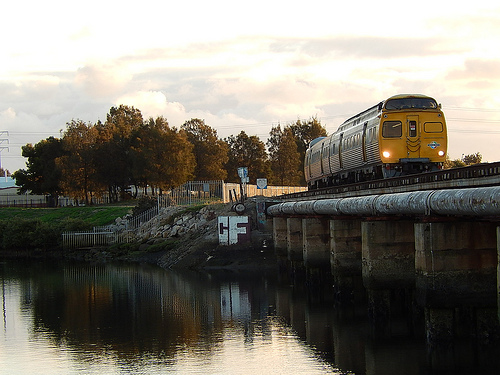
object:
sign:
[256, 178, 269, 190]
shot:
[0, 0, 499, 374]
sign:
[236, 166, 249, 178]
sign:
[240, 176, 250, 183]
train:
[300, 90, 451, 192]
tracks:
[267, 160, 499, 199]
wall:
[153, 202, 272, 273]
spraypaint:
[220, 182, 309, 204]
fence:
[59, 177, 226, 251]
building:
[0, 174, 24, 189]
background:
[1, 0, 302, 205]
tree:
[49, 116, 130, 206]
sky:
[1, 0, 499, 175]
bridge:
[268, 162, 499, 298]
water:
[0, 255, 498, 374]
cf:
[216, 213, 250, 247]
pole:
[0, 128, 10, 152]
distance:
[0, 0, 499, 205]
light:
[381, 150, 392, 160]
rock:
[176, 216, 188, 225]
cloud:
[112, 85, 255, 140]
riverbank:
[0, 206, 127, 249]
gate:
[60, 222, 125, 250]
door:
[406, 114, 421, 161]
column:
[409, 218, 498, 317]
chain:
[405, 135, 422, 153]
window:
[380, 119, 404, 139]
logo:
[426, 140, 442, 150]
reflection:
[216, 280, 258, 324]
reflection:
[0, 265, 352, 375]